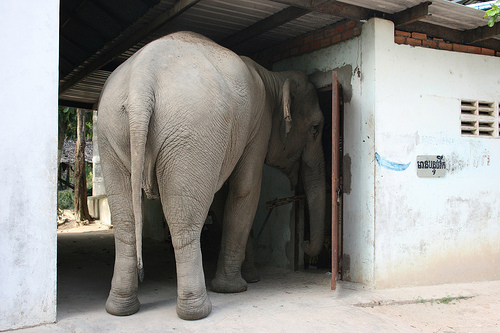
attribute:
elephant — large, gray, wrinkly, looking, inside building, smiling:
[97, 31, 324, 320]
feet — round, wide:
[95, 268, 259, 321]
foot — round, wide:
[175, 304, 211, 321]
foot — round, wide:
[103, 299, 142, 315]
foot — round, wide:
[207, 279, 248, 295]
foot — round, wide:
[240, 270, 260, 283]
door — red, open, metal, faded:
[330, 77, 340, 291]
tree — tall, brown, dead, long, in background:
[74, 108, 93, 223]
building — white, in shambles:
[59, 2, 499, 286]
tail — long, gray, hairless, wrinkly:
[127, 90, 156, 284]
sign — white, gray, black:
[414, 155, 447, 179]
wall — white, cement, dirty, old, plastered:
[373, 19, 497, 288]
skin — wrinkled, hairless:
[97, 30, 328, 320]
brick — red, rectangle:
[394, 28, 411, 38]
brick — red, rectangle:
[410, 32, 426, 40]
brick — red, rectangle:
[405, 38, 420, 48]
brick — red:
[421, 38, 436, 47]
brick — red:
[437, 42, 453, 51]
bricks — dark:
[395, 29, 498, 58]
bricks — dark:
[231, 19, 361, 61]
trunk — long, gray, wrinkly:
[300, 149, 328, 256]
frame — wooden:
[218, 0, 427, 47]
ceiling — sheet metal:
[60, 0, 490, 113]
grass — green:
[85, 169, 92, 189]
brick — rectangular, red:
[453, 44, 467, 54]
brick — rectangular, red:
[469, 45, 482, 53]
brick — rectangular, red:
[481, 49, 494, 56]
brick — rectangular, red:
[340, 27, 362, 40]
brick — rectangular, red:
[327, 34, 343, 45]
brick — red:
[343, 19, 359, 27]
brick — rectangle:
[327, 21, 346, 35]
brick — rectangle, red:
[302, 30, 323, 41]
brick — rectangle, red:
[309, 39, 333, 49]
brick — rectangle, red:
[287, 47, 303, 58]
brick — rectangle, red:
[263, 44, 286, 51]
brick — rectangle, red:
[250, 53, 266, 63]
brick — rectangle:
[395, 36, 405, 43]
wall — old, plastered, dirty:
[273, 20, 376, 285]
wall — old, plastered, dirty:
[253, 163, 302, 268]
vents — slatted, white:
[459, 99, 499, 140]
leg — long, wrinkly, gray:
[156, 157, 219, 321]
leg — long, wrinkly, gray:
[101, 158, 144, 315]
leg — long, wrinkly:
[213, 143, 248, 294]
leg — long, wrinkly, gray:
[244, 232, 261, 281]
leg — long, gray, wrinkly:
[210, 166, 263, 293]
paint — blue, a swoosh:
[374, 151, 411, 172]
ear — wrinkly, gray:
[283, 78, 298, 137]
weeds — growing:
[55, 190, 77, 208]